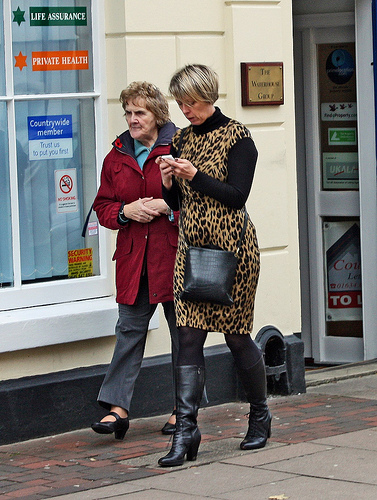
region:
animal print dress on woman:
[164, 121, 263, 335]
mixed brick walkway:
[0, 382, 374, 498]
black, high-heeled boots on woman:
[158, 337, 275, 470]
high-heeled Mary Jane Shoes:
[89, 404, 129, 444]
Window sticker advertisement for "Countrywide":
[27, 113, 77, 159]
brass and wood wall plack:
[238, 59, 285, 105]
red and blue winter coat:
[87, 120, 175, 305]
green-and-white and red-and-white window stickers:
[9, 2, 93, 76]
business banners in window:
[315, 37, 368, 341]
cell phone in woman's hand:
[158, 153, 175, 163]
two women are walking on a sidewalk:
[91, 62, 286, 467]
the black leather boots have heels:
[156, 352, 274, 467]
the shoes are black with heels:
[84, 403, 189, 442]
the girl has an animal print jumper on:
[170, 120, 258, 335]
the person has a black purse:
[176, 122, 251, 308]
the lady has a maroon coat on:
[88, 120, 176, 306]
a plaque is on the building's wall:
[236, 52, 295, 134]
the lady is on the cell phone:
[151, 62, 223, 206]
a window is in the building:
[2, 0, 125, 331]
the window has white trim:
[2, 0, 112, 303]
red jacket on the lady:
[91, 120, 179, 305]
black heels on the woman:
[90, 404, 180, 440]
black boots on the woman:
[155, 351, 273, 467]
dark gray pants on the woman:
[96, 274, 177, 409]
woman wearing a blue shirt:
[131, 139, 157, 170]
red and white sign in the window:
[28, 47, 91, 72]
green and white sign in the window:
[27, 4, 87, 27]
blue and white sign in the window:
[25, 113, 75, 162]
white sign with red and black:
[52, 166, 80, 213]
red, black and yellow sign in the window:
[65, 247, 94, 278]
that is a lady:
[101, 77, 181, 438]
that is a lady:
[162, 71, 257, 473]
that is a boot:
[169, 356, 195, 468]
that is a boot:
[243, 347, 268, 448]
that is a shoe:
[86, 411, 135, 433]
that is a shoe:
[159, 413, 171, 439]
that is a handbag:
[177, 245, 244, 298]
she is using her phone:
[148, 147, 194, 174]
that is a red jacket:
[118, 237, 134, 289]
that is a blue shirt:
[137, 140, 149, 158]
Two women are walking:
[77, 54, 289, 471]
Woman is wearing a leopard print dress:
[154, 57, 265, 342]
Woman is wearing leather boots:
[151, 343, 279, 472]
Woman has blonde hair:
[159, 52, 226, 136]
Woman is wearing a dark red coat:
[78, 118, 190, 308]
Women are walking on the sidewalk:
[0, 56, 375, 497]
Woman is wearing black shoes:
[85, 393, 198, 444]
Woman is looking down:
[162, 55, 229, 134]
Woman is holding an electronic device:
[146, 146, 202, 201]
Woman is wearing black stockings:
[169, 326, 270, 374]